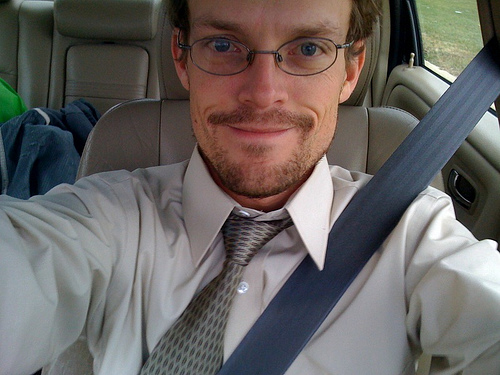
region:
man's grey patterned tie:
[124, 196, 282, 373]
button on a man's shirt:
[236, 277, 250, 294]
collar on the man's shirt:
[177, 134, 344, 274]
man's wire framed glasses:
[166, 22, 366, 82]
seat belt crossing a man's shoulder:
[222, 48, 499, 363]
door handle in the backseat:
[443, 166, 477, 208]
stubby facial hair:
[183, 99, 338, 200]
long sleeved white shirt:
[1, 140, 498, 374]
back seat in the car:
[0, 0, 383, 145]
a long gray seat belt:
[174, 47, 499, 374]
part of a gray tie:
[140, 211, 287, 373]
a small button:
[235, 275, 250, 293]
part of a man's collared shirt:
[0, 139, 498, 374]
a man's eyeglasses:
[170, 28, 362, 80]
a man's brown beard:
[193, 106, 323, 201]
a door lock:
[407, 52, 416, 67]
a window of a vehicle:
[404, 0, 494, 110]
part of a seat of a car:
[86, 95, 194, 180]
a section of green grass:
[417, 3, 483, 81]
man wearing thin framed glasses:
[160, 33, 431, 96]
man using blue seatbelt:
[256, 306, 306, 348]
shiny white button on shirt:
[233, 271, 256, 301]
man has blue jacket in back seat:
[16, 83, 83, 172]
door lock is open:
[388, 38, 426, 88]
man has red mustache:
[203, 105, 303, 140]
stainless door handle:
[453, 169, 485, 209]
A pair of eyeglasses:
[172, 22, 359, 79]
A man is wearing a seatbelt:
[1, 2, 498, 372]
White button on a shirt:
[230, 275, 254, 298]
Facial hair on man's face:
[198, 103, 329, 203]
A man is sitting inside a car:
[1, 1, 498, 372]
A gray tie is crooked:
[134, 208, 295, 373]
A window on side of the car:
[412, 0, 483, 85]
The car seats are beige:
[1, 2, 446, 192]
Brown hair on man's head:
[161, 0, 385, 65]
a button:
[236, 282, 248, 292]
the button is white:
[233, 279, 250, 292]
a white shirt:
[371, 273, 426, 372]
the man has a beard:
[251, 169, 278, 194]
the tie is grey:
[181, 318, 217, 373]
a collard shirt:
[296, 202, 328, 238]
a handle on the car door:
[448, 174, 480, 206]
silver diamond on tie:
[149, 350, 159, 360]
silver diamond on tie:
[154, 355, 164, 363]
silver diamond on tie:
[160, 358, 170, 366]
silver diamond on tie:
[166, 359, 175, 374]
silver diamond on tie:
[168, 331, 177, 341]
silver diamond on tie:
[171, 333, 183, 349]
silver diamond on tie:
[182, 331, 189, 343]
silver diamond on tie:
[196, 324, 206, 335]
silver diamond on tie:
[223, 282, 233, 294]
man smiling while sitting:
[2, 5, 494, 374]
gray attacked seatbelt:
[178, 36, 488, 355]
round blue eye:
[298, 33, 323, 61]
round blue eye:
[207, 34, 236, 59]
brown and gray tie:
[130, 179, 269, 372]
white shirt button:
[232, 269, 250, 301]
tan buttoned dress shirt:
[7, 145, 498, 368]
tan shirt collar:
[174, 150, 346, 280]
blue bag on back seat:
[9, 98, 113, 198]